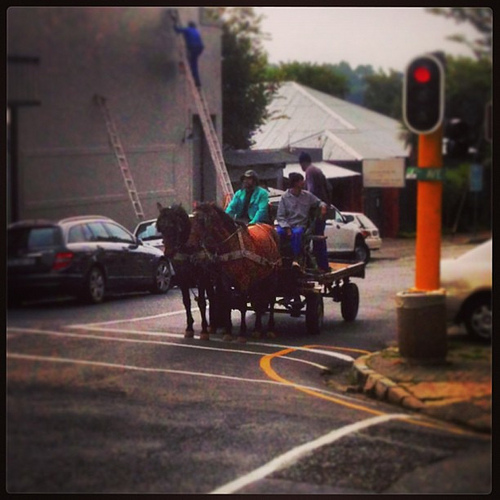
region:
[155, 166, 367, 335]
men on cart with horses pulling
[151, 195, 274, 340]
horses pulling a cart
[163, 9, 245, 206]
man on a ladder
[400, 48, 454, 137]
light on corner of street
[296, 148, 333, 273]
man standing on cart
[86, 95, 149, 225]
ladder without person on it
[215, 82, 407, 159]
roof of structure on street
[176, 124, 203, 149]
light on side of building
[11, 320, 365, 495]
street for pedestrians and vehicles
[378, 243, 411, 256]
sidewalk area for pedestrians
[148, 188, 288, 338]
Horses pulling a carriage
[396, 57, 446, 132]
Red light on traffic sign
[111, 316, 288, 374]
White paint on the ground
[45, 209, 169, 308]
Car parked on the street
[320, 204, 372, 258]
White jeep parked on the street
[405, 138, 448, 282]
Orange pole on traffic light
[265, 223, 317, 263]
Man wearing blue pants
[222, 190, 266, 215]
man wearing a green jacket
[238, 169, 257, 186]
Man wearing a hat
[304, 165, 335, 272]
Man standing on a platfrom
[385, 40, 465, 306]
a red traffic light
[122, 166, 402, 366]
a horse drawn tractor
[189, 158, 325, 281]
two people on horse drawn tractor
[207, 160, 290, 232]
man in blue coat and black hat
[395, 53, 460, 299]
an orange pole with traffic light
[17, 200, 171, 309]
a station wagon parked at curb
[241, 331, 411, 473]
a yellow line on the road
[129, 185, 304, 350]
two brown horses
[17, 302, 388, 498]
white lines on the road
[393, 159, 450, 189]
a green street sign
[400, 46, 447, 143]
traffic light on corner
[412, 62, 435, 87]
red light signal on traffic light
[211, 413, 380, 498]
white painted line in the street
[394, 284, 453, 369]
small trash can on corner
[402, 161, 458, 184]
green street sign on pole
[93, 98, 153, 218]
ladder standing against building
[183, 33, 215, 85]
person standing on ladder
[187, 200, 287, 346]
brown horse pulling cart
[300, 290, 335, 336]
left front wheel on cart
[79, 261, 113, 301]
rear right tire on grey car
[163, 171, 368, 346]
Horse walking on the road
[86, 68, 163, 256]
Tall white latter on buidling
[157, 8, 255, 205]
Tall white latter on buidling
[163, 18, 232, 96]
man climbing a ladder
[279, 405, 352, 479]
White line on pavement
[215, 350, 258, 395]
White line on pavement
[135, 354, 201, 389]
White line on pavement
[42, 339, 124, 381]
White line on pavement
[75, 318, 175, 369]
White line on pavement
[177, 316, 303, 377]
White line on pavement